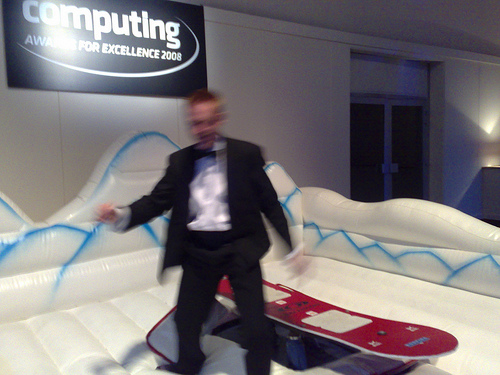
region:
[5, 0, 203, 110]
black sign on wall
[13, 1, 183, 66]
white letters on sign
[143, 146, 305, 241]
man's jacket is black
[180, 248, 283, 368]
man's pants are black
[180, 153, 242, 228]
man's shirt is white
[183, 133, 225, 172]
man wearing a bow tie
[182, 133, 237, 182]
the bow tie is black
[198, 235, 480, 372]
snowboard behind the man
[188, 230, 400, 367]
the snowboard is red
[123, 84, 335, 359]
man standing in inflatable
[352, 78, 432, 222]
Double glass door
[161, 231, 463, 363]
a snow board game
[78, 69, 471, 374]
A guy in a tux who fell off a snow board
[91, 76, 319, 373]
A guy wearing a black tux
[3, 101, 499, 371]
A snow board fake game set with fake mountains and snow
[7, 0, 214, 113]
A sign for an event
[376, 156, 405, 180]
Door knobs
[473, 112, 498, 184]
A light that is turned on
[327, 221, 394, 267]
Fake blue mountains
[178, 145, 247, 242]
A white dress shirt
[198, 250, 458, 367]
giant red skateboard behind a man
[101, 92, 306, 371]
a man standing on a blowup surface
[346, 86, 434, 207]
double doors behind the blow up structure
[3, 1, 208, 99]
sign on the wall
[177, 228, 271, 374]
black pants the man is wearing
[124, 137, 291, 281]
black jacket the man is wearing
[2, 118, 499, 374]
blowup bouncy structure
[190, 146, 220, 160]
man's black tie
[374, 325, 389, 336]
bolt on the giant skateboard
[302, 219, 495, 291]
jagged blue lines on the white plastic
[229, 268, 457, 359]
a red snowboard on a plastic sofa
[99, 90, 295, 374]
a blurred image of a man in a tuxedo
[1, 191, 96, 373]
a plastic air-filled sofa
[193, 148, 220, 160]
the mans black bow tie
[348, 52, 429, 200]
a store fronts double doors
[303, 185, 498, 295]
a white and blue back rest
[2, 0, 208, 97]
an advertisement display above the man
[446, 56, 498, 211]
a light in the corner of the room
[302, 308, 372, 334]
the snowboards foot strap mounting area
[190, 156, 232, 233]
the man is wearing a white dress shirt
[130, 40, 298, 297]
a man in a tux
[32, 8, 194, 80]
a black in white sign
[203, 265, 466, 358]
a red and white board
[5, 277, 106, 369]
white air cushion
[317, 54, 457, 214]
a double door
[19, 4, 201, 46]
a sign saying computing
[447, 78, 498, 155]
light and shadow on the wall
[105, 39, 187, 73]
a sign saying excellence in 2008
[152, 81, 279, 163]
a very blurry face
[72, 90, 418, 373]
a man on an air bag of sorts